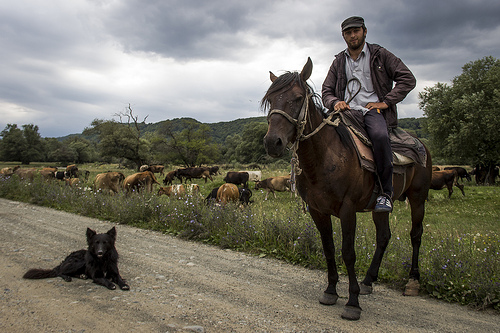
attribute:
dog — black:
[19, 220, 133, 294]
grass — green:
[440, 197, 484, 233]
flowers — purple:
[171, 211, 215, 235]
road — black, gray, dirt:
[1, 196, 484, 331]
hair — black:
[259, 67, 300, 113]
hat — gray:
[336, 13, 368, 32]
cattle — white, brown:
[151, 182, 205, 204]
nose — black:
[261, 129, 288, 157]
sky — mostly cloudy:
[0, 1, 485, 144]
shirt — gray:
[337, 45, 380, 120]